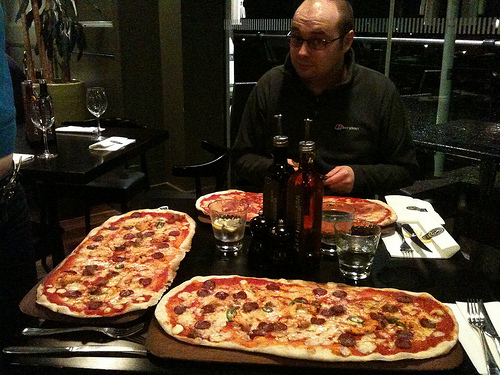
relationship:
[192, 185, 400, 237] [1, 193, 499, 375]
pizza on table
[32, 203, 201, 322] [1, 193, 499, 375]
pizza on table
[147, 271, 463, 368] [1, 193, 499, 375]
pizza on table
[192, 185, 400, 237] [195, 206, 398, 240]
pizza resting on board